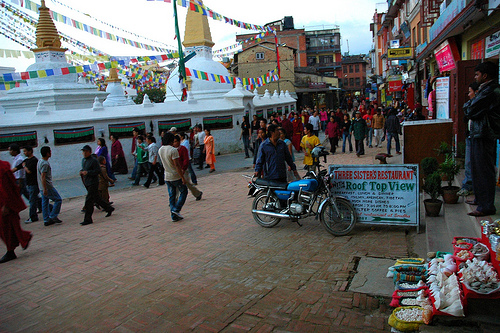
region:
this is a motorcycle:
[248, 174, 341, 233]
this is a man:
[156, 131, 189, 233]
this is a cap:
[83, 142, 89, 149]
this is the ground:
[73, 242, 185, 295]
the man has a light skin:
[174, 159, 177, 168]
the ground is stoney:
[108, 262, 182, 314]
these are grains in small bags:
[396, 275, 423, 322]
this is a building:
[193, 55, 236, 110]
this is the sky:
[348, 9, 361, 26]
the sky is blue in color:
[349, 27, 362, 37]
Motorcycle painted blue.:
[239, 160, 359, 241]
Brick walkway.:
[31, 221, 351, 331]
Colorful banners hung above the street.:
[9, 15, 301, 97]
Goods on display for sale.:
[379, 225, 499, 330]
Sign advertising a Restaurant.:
[329, 162, 422, 231]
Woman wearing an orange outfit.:
[198, 124, 224, 180]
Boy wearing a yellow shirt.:
[298, 122, 326, 173]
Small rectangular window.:
[50, 122, 101, 144]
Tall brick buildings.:
[239, 17, 376, 118]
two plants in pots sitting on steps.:
[421, 138, 466, 225]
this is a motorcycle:
[253, 170, 336, 224]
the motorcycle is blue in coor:
[253, 172, 330, 227]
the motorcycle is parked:
[244, 169, 335, 235]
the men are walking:
[154, 129, 182, 229]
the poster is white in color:
[359, 169, 410, 224]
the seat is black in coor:
[257, 179, 281, 183]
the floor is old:
[8, 253, 330, 325]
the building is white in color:
[1, 99, 126, 122]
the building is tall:
[235, 46, 290, 66]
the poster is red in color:
[437, 47, 449, 67]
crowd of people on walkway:
[320, 87, 409, 150]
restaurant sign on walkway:
[322, 161, 424, 231]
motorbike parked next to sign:
[244, 155, 358, 240]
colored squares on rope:
[187, 63, 284, 91]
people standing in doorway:
[448, 57, 492, 219]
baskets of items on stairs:
[392, 242, 479, 321]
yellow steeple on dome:
[25, 7, 68, 57]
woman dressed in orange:
[198, 126, 222, 178]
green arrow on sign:
[364, 213, 411, 231]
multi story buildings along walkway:
[377, 14, 437, 101]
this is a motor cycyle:
[245, 170, 355, 236]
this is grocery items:
[399, 231, 484, 325]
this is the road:
[85, 236, 243, 303]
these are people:
[284, 104, 389, 146]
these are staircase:
[419, 187, 492, 245]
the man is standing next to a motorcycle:
[236, 118, 351, 221]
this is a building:
[266, 16, 421, 79]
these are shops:
[404, 27, 494, 224]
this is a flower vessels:
[422, 194, 457, 226]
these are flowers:
[420, 138, 460, 215]